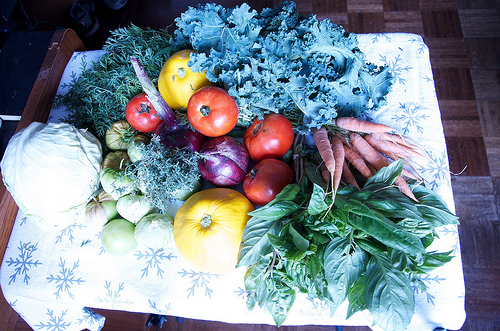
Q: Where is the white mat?
A: On the floor.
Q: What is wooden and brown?
A: Floor.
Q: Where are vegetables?
A: On a mat.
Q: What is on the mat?
A: Red onions.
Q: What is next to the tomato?
A: Green vegetable.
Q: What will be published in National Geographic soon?
A: The photo will.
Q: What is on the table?
A: The vegetables.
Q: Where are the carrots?
A: In a pile.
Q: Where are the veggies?
A: On table.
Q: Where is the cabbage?
A: Left on table.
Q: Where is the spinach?
A: On table.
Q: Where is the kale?
A: On table.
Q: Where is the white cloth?
A: On table.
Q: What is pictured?
A: Vegetables.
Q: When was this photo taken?
A: Daytime.